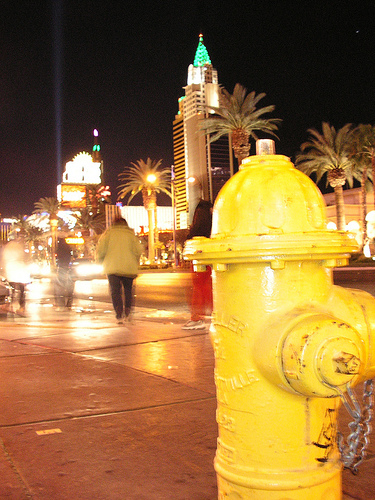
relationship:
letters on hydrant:
[212, 311, 268, 416] [200, 139, 371, 499]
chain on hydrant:
[342, 387, 374, 470] [200, 139, 371, 499]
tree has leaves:
[206, 82, 267, 162] [201, 82, 284, 133]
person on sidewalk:
[96, 210, 144, 321] [3, 292, 216, 498]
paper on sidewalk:
[37, 424, 67, 437] [3, 292, 216, 498]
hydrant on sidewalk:
[200, 139, 371, 499] [3, 292, 216, 498]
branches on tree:
[203, 93, 230, 140] [206, 82, 267, 162]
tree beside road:
[206, 82, 267, 162] [63, 270, 212, 320]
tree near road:
[206, 82, 267, 162] [63, 270, 212, 320]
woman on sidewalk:
[96, 210, 144, 321] [3, 292, 216, 498]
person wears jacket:
[94, 212, 144, 321] [102, 227, 143, 274]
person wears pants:
[94, 212, 144, 321] [109, 270, 136, 313]